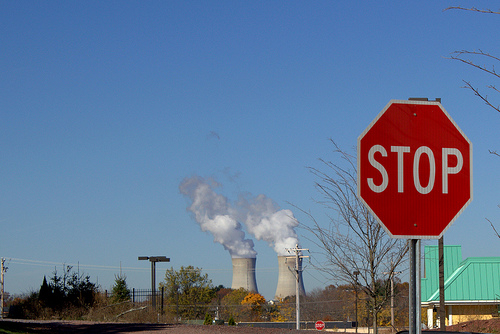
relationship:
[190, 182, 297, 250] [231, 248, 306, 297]
pollution eminating from stacks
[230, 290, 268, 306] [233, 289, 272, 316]
leaves are attached to trees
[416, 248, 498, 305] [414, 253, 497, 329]
roof attached to building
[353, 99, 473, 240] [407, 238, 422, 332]
sign connected to pole